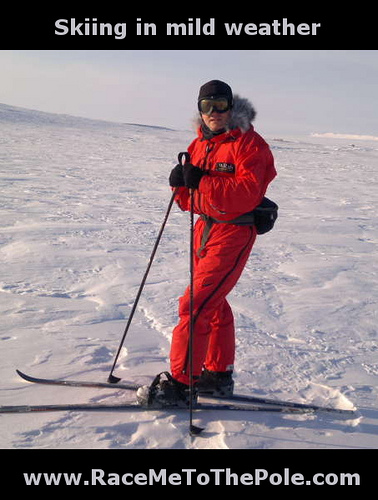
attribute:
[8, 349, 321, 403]
ski — skier's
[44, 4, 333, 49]
sign — skiing in mild winter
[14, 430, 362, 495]
website — Race Me To The Pole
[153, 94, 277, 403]
outfit — red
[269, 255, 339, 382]
snow — white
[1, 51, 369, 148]
sky — blue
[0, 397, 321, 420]
ski — skier's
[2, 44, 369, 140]
sky — blue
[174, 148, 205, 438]
ski pole — skier's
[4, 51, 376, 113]
clouds — white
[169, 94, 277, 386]
snowsuit — red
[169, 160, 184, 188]
right hand — skier's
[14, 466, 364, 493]
www address — black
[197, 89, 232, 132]
guys face — guy's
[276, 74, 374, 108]
sky — blue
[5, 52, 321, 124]
sky — blue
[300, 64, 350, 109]
cloud — white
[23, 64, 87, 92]
cloud — white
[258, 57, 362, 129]
sky — blue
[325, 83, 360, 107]
sky — blue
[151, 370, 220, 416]
left boot — skier's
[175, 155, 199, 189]
left hand — skier's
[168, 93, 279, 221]
coat — orange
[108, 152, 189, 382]
ski pole — skier's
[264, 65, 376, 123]
clouds — white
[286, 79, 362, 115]
clouds — white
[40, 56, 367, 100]
clouds — white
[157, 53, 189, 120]
sky — blue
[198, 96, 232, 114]
goggles — ski, skier's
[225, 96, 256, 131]
hood — fur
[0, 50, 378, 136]
clouds — white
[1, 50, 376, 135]
sky — blue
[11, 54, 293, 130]
cloud — white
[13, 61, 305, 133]
cloud — white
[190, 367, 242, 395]
foot — skier's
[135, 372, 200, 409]
foot — skier's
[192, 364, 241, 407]
shoe — snow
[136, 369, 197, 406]
shoe — snow